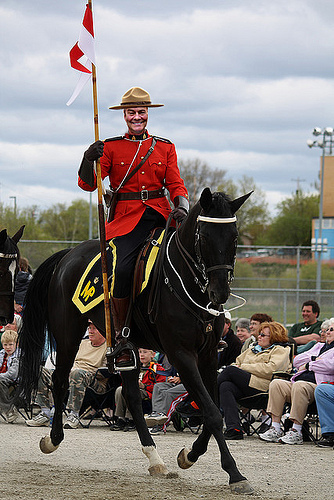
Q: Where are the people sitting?
A: In chairs.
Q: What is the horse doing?
A: Trotting.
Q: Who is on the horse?
A: A man.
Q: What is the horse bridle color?
A: White.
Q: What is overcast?
A: Sky.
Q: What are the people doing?
A: Sitting.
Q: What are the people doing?
A: Watching.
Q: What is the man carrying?
A: Flag.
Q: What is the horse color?
A: Black.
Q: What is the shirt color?
A: Red.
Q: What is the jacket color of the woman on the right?
A: Pink.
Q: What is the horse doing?
A: Trotting.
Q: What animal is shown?
A: A horse.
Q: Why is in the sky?
A: Clouds.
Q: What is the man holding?
A: A flag.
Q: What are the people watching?
A: A parade of horseman.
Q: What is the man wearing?
A: A red coat.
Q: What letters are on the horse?
A: MP.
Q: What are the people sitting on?
A: Chairs.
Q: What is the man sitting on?
A: Horse.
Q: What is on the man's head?
A: Hat.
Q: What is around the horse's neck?
A: Rope.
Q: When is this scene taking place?
A: Day time.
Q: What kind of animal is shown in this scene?
A: Horse.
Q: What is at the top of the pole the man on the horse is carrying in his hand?
A: Flag.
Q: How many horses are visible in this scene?
A: Two.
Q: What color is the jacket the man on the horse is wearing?
A: Red and black.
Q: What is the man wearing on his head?
A: Hat.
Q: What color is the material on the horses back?
A: Black and yellow.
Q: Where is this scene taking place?
A: At a parade.